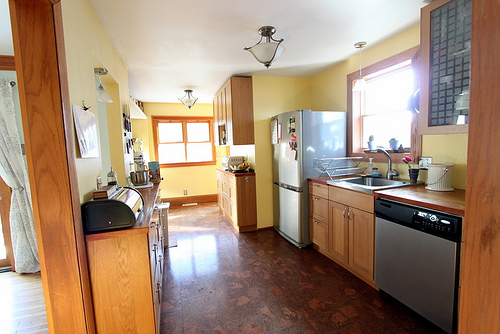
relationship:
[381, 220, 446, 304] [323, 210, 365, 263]
dishwasher near cabinet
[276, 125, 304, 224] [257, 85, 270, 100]
refrigerator near wall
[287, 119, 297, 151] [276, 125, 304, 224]
magnets on refrigerator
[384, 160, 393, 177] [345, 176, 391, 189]
faucet on sink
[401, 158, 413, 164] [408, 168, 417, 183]
flower in vase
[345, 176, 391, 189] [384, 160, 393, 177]
sink has faucet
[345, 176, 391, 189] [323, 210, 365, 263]
sink above cabinet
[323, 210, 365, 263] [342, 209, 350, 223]
cabinet has handles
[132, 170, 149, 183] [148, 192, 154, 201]
bowl on counter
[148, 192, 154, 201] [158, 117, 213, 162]
counter near window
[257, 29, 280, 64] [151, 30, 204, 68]
light on ceiling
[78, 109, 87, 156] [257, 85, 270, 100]
picture on wall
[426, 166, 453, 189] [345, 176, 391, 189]
pot near sink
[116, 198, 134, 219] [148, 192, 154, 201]
breadbox on counter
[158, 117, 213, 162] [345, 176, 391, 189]
window near sink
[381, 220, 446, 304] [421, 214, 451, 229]
dishwasher has buttons